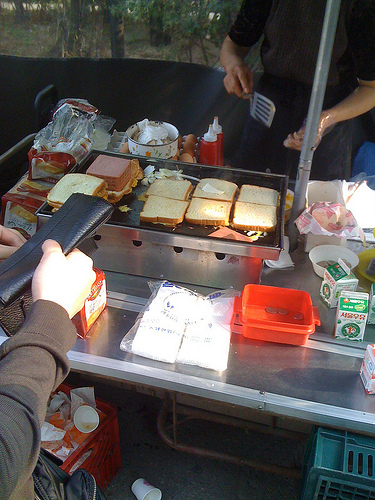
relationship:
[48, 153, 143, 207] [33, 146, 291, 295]
sandwiches on grill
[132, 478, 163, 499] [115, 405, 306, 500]
cup on ground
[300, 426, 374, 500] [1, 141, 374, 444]
crate under table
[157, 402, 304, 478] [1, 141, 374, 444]
bar under table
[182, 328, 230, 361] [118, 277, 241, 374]
napkins in package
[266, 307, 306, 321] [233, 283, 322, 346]
quarters in box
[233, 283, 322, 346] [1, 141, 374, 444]
box on table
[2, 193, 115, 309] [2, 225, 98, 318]
wallet in hands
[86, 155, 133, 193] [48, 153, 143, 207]
meat for sandwiches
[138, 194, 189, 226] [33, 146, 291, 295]
bread on grill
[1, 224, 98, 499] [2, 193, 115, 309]
person holding wallet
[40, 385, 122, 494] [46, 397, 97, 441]
crate with rubbish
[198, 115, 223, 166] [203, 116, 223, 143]
bottles with tops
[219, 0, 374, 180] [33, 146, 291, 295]
person behind grill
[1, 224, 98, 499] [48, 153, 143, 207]
person making sandwiches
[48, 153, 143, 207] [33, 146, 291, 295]
sandwiches cooked on grill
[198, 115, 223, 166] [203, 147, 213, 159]
bottles of ketchup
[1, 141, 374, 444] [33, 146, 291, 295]
table under grill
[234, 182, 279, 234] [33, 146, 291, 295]
sandwich on grill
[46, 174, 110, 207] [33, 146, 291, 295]
sandwich on grill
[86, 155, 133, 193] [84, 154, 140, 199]
meat in stack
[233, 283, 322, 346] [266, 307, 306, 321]
box with quarters